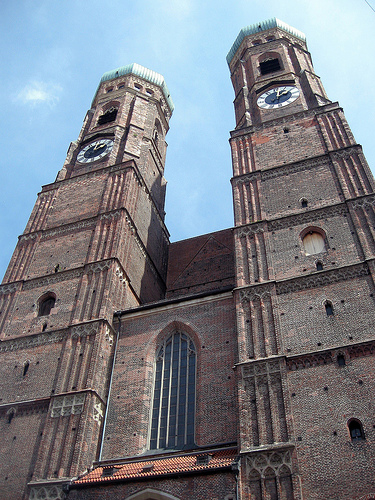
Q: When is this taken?
A: Daytime.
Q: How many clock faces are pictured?
A: Two.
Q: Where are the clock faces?
A: On the towers.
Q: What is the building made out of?
A: Brick.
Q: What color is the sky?
A: Blue.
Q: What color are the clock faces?
A: Black and white.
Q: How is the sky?
A: Clear.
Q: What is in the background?
A: The sky.